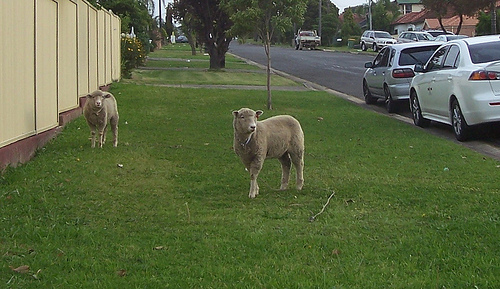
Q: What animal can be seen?
A: Sheep.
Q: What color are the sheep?
A: Gray.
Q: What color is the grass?
A: Green.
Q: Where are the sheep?
A: On the grass.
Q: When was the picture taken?
A: Daytime.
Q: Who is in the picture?
A: No one.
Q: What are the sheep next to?
A: A wall.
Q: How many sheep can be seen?
A: 2.